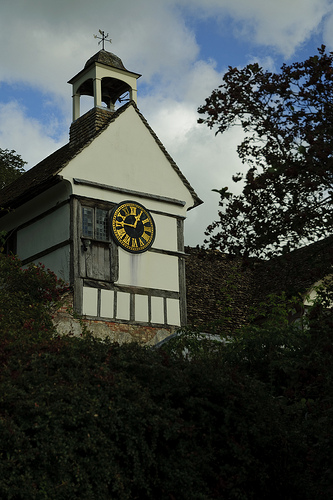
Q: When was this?
A: Daytime.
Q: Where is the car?
A: No car seen.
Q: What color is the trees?
A: Green.